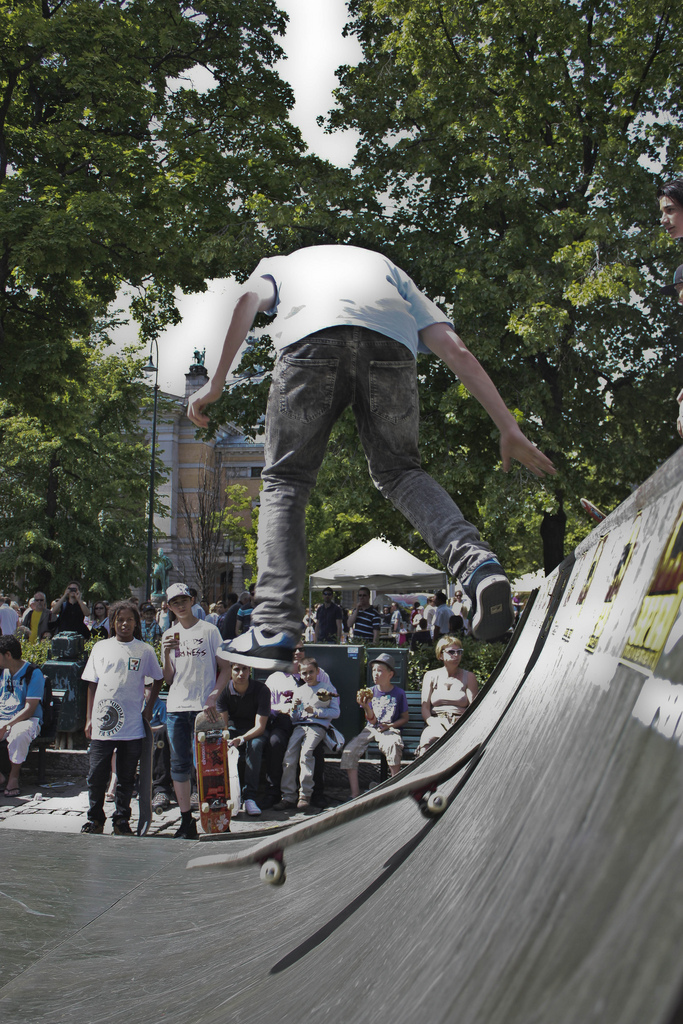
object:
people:
[82, 581, 232, 838]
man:
[185, 243, 557, 672]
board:
[186, 740, 482, 885]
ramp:
[232, 446, 683, 1023]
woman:
[419, 633, 478, 757]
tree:
[316, 0, 682, 594]